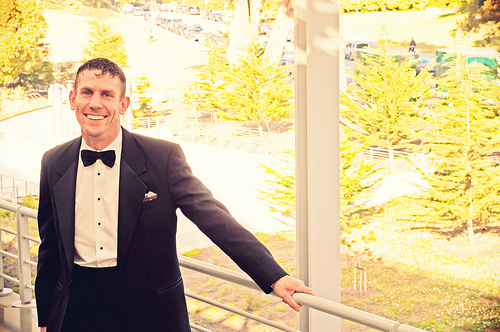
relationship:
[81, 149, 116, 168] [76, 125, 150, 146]
bow tie on collar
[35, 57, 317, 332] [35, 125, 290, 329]
man in suit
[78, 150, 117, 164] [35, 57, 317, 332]
bow tie on man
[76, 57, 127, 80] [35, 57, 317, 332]
hair on man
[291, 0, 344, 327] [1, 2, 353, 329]
gray pole on building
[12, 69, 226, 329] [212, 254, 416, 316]
man holding rail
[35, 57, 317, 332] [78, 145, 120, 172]
man wearing bow tie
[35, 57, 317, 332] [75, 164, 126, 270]
man wearing white shirt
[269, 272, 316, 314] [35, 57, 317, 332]
hand of man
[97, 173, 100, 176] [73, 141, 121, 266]
black button on shirt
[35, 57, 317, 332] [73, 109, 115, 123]
man has mouth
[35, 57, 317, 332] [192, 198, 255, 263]
man has arm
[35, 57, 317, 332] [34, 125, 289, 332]
man dress suit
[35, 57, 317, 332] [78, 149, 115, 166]
man has bow tie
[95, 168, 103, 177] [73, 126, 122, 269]
black button on shirt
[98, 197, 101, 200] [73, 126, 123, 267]
button on shirt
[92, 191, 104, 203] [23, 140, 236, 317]
button on shirt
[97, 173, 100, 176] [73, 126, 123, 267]
black button on shirt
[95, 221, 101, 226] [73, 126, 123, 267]
button on shirt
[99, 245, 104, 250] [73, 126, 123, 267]
button on shirt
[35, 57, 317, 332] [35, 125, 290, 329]
man wearing suit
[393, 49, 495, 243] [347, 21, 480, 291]
tree in background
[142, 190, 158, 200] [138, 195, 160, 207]
hankerchief in pocket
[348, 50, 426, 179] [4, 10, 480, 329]
tree outside window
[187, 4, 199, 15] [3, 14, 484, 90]
vehicle? in background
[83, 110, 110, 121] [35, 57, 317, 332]
smile of a man